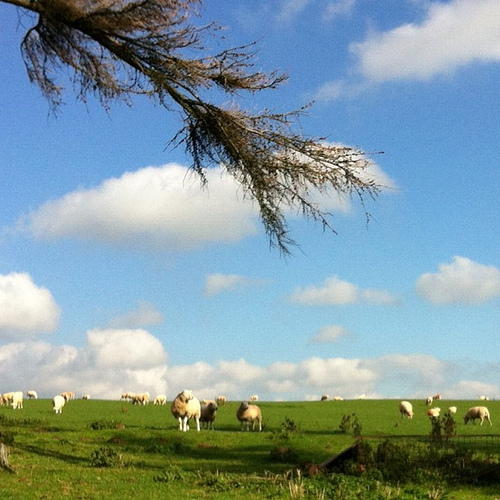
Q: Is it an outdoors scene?
A: Yes, it is outdoors.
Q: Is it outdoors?
A: Yes, it is outdoors.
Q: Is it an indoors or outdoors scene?
A: It is outdoors.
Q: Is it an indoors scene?
A: No, it is outdoors.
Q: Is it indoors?
A: No, it is outdoors.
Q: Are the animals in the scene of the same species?
A: Yes, all the animals are sheep.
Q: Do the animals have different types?
A: No, all the animals are sheep.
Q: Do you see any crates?
A: No, there are no crates.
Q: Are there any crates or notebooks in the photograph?
A: No, there are no crates or notebooks.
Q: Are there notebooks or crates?
A: No, there are no crates or notebooks.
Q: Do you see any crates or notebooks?
A: No, there are no crates or notebooks.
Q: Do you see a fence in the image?
A: Yes, there is a fence.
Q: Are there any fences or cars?
A: Yes, there is a fence.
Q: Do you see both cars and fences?
A: No, there is a fence but no cars.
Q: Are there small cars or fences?
A: Yes, there is a small fence.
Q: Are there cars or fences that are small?
A: Yes, the fence is small.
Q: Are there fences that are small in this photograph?
A: Yes, there is a small fence.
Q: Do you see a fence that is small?
A: Yes, there is a fence that is small.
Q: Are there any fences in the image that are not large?
A: Yes, there is a small fence.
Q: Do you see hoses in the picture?
A: No, there are no hoses.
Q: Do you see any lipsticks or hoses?
A: No, there are no hoses or lipsticks.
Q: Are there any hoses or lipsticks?
A: No, there are no hoses or lipsticks.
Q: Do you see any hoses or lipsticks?
A: No, there are no hoses or lipsticks.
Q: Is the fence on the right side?
A: Yes, the fence is on the right of the image.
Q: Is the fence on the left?
A: No, the fence is on the right of the image.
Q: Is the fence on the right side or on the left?
A: The fence is on the right of the image.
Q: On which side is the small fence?
A: The fence is on the right of the image.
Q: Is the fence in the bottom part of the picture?
A: Yes, the fence is in the bottom of the image.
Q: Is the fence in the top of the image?
A: No, the fence is in the bottom of the image.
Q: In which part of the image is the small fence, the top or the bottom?
A: The fence is in the bottom of the image.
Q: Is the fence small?
A: Yes, the fence is small.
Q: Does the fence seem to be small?
A: Yes, the fence is small.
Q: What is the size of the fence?
A: The fence is small.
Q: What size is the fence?
A: The fence is small.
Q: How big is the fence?
A: The fence is small.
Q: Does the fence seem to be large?
A: No, the fence is small.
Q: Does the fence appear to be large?
A: No, the fence is small.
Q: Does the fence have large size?
A: No, the fence is small.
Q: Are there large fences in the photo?
A: No, there is a fence but it is small.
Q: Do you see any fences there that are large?
A: No, there is a fence but it is small.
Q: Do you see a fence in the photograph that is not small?
A: No, there is a fence but it is small.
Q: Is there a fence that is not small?
A: No, there is a fence but it is small.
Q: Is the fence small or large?
A: The fence is small.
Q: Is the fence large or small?
A: The fence is small.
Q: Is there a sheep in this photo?
A: Yes, there is a sheep.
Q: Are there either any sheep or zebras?
A: Yes, there is a sheep.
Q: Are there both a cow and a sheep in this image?
A: No, there is a sheep but no cows.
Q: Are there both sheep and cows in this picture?
A: No, there is a sheep but no cows.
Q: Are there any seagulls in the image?
A: No, there are no seagulls.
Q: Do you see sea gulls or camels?
A: No, there are no sea gulls or camels.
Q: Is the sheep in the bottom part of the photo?
A: Yes, the sheep is in the bottom of the image.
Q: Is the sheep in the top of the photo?
A: No, the sheep is in the bottom of the image.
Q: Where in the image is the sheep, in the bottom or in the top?
A: The sheep is in the bottom of the image.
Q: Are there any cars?
A: No, there are no cars.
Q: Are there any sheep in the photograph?
A: Yes, there is a sheep.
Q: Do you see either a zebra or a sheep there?
A: Yes, there is a sheep.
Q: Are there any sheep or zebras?
A: Yes, there is a sheep.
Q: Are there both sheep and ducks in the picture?
A: No, there is a sheep but no ducks.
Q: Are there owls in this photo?
A: No, there are no owls.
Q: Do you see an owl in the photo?
A: No, there are no owls.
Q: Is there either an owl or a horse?
A: No, there are no owls or horses.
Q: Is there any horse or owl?
A: No, there are no owls or horses.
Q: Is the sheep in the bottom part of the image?
A: Yes, the sheep is in the bottom of the image.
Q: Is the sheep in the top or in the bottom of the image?
A: The sheep is in the bottom of the image.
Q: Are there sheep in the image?
A: Yes, there is a sheep.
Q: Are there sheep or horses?
A: Yes, there is a sheep.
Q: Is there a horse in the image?
A: No, there are no horses.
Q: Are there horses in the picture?
A: No, there are no horses.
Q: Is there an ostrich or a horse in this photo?
A: No, there are no horses or ostriches.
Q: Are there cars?
A: No, there are no cars.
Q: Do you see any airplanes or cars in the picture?
A: No, there are no cars or airplanes.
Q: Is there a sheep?
A: Yes, there is a sheep.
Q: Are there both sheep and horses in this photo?
A: No, there is a sheep but no horses.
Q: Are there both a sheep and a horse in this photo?
A: No, there is a sheep but no horses.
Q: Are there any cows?
A: No, there are no cows.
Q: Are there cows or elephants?
A: No, there are no cows or elephants.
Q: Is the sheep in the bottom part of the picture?
A: Yes, the sheep is in the bottom of the image.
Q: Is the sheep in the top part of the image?
A: No, the sheep is in the bottom of the image.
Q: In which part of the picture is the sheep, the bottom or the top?
A: The sheep is in the bottom of the image.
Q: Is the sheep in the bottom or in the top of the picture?
A: The sheep is in the bottom of the image.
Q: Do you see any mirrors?
A: No, there are no mirrors.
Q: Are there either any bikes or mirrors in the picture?
A: No, there are no mirrors or bikes.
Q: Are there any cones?
A: No, there are no cones.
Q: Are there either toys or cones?
A: No, there are no cones or toys.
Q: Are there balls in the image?
A: No, there are no balls.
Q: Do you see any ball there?
A: No, there are no balls.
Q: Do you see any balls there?
A: No, there are no balls.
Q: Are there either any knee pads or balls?
A: No, there are no balls or knee pads.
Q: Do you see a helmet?
A: No, there are no helmets.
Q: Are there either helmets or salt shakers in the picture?
A: No, there are no helmets or salt shakers.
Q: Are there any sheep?
A: Yes, there is a sheep.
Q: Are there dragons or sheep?
A: Yes, there is a sheep.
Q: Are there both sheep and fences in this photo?
A: Yes, there are both a sheep and a fence.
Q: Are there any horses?
A: No, there are no horses.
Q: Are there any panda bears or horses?
A: No, there are no horses or panda bears.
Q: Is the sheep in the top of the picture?
A: No, the sheep is in the bottom of the image.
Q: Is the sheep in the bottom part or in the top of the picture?
A: The sheep is in the bottom of the image.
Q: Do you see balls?
A: No, there are no balls.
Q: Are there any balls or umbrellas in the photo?
A: No, there are no balls or umbrellas.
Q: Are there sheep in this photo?
A: Yes, there is a sheep.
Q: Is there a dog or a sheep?
A: Yes, there is a sheep.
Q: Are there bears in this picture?
A: No, there are no bears.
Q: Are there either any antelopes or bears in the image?
A: No, there are no bears or antelopes.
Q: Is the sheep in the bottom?
A: Yes, the sheep is in the bottom of the image.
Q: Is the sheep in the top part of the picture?
A: No, the sheep is in the bottom of the image.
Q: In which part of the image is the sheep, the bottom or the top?
A: The sheep is in the bottom of the image.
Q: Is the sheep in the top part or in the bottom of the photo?
A: The sheep is in the bottom of the image.